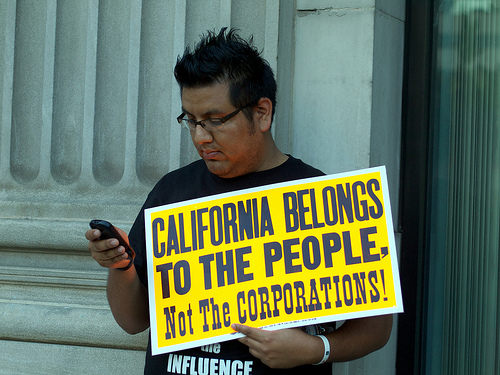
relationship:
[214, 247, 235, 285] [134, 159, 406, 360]
letter on sign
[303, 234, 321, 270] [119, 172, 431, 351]
letter on a sign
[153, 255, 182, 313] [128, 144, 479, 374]
letter on sign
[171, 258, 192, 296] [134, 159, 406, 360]
letter on sign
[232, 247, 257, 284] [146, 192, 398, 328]
letter on sign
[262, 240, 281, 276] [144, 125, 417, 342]
letter on sign